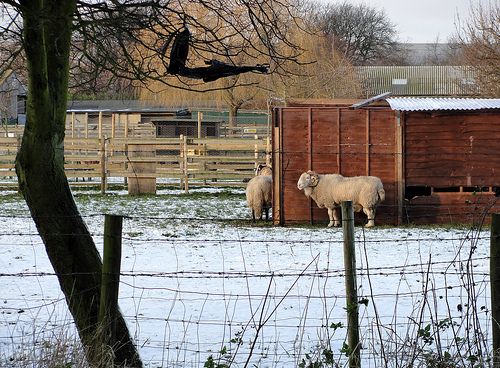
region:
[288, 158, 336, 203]
the head of a sheep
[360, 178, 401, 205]
the tail of a sheep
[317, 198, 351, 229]
the legs of a sheep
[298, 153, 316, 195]
the eye of a sheep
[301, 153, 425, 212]
the body of a sheep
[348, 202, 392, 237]
the back legs of a sheep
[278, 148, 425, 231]
a sheep in the snow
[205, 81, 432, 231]
a sheep near a fence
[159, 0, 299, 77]
a tree with no leaves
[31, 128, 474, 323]
a sheep near a tree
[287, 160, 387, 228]
this is a sheep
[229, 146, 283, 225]
this is a sheep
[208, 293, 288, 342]
this is snow on the ground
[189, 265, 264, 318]
this is snow on the ground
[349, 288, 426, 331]
this is snow on the ground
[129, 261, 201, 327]
this is snow on the ground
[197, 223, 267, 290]
this is snow on the ground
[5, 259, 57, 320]
this is snow on the ground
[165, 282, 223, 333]
this is snow on the ground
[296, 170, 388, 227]
white sheep standing in snow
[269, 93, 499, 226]
red out building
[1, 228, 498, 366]
chicken wire fence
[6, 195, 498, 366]
thin layer of snow on ground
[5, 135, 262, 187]
wooden slats on fence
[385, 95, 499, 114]
silver tin crimped roof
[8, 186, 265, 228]
grass showing through snow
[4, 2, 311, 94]
tree bare of leaves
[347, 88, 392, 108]
wood plank on roof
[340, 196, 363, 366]
grey metal fence post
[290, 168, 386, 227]
A lamb standing in front of a wooden wall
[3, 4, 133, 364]
A thick bending tree trunk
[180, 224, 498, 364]
A haphazardly constructed wire fence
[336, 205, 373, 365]
A tall thin metal fence post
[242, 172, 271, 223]
The back of a fluffy white lamb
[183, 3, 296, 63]
Some thin leafless branches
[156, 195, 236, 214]
Some patchy grass poking through snow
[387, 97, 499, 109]
A corrugated tin roof with a light covering of snow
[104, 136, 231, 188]
A tan wooden fence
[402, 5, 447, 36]
A gray empty sky